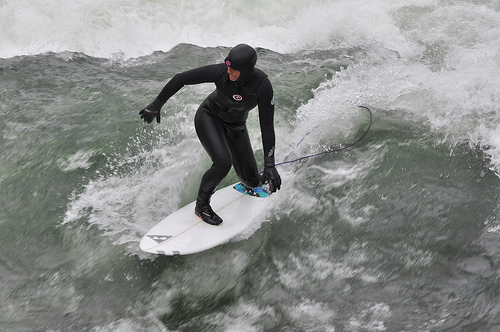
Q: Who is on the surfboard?
A: A man.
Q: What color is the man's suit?
A: Black.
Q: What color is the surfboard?
A: White.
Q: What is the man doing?
A: Surfing.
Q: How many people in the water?
A: One.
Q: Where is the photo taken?
A: At the beach.